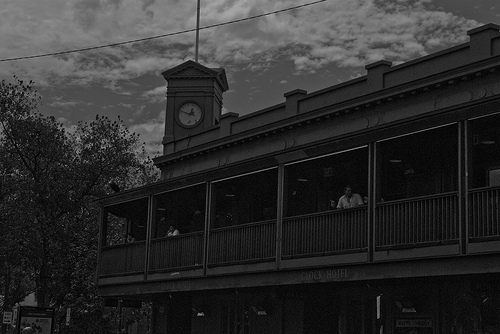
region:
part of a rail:
[410, 208, 421, 223]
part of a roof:
[363, 88, 372, 115]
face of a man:
[349, 190, 356, 205]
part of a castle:
[196, 73, 206, 81]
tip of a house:
[200, 105, 210, 115]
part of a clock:
[191, 121, 201, 132]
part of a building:
[257, 300, 272, 312]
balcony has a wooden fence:
[96, 181, 497, 263]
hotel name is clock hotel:
[295, 262, 356, 286]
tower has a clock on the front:
[146, 54, 232, 148]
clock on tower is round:
[174, 101, 211, 134]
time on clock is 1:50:
[166, 93, 208, 135]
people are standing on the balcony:
[108, 180, 383, 245]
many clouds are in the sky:
[6, 5, 451, 77]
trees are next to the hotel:
[0, 79, 149, 321]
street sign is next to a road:
[1, 308, 18, 332]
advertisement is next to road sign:
[13, 300, 65, 331]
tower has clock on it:
[156, 60, 231, 145]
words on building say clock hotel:
[298, 268, 360, 288]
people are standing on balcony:
[293, 168, 393, 242]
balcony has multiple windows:
[88, 110, 498, 257]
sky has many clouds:
[3, 6, 456, 48]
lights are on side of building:
[163, 290, 413, 318]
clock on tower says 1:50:
[174, 98, 213, 134]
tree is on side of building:
[3, 72, 141, 291]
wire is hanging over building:
[7, 4, 339, 83]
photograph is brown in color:
[5, 8, 482, 320]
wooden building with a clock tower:
[130, 30, 455, 290]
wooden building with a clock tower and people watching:
[110, 35, 455, 290]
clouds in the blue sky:
[50, 60, 145, 95]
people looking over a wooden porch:
[120, 145, 445, 290]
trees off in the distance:
[15, 90, 95, 260]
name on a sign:
[10, 276, 75, 321]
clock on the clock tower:
[172, 95, 202, 130]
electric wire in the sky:
[35, 30, 127, 75]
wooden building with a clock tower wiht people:
[44, 20, 463, 310]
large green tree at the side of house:
[30, 162, 98, 250]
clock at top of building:
[171, 95, 212, 130]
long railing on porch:
[196, 220, 403, 258]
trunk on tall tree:
[21, 246, 66, 317]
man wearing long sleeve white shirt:
[327, 189, 373, 213]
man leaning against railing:
[159, 217, 191, 246]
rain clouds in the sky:
[247, 21, 322, 80]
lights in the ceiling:
[381, 153, 430, 185]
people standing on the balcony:
[136, 172, 377, 232]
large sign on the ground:
[13, 299, 61, 321]